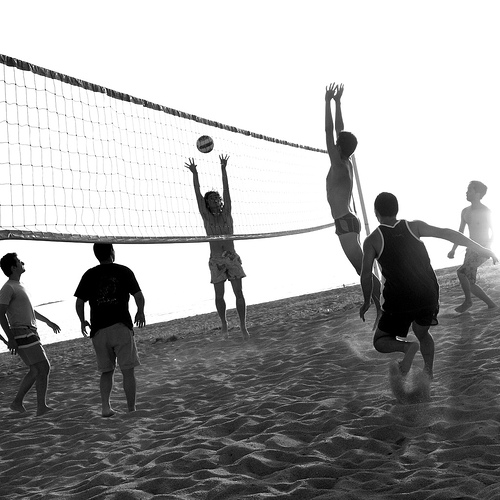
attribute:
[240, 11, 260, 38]
sky — clear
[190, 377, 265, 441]
sand — bumpy, kicked, covered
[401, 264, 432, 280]
shirt — black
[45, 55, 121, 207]
net — up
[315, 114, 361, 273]
man — jumping, standing, running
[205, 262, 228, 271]
swim trunks — striped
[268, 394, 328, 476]
beach — sandy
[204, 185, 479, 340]
men — playing, watching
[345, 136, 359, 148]
hair — short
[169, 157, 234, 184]
arms — raised, up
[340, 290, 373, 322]
foot — raised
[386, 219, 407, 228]
tank top — white, black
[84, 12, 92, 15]
sun — shining